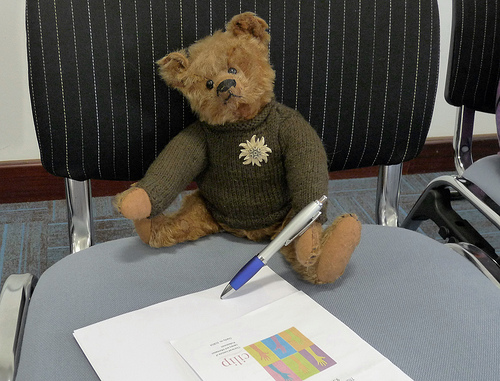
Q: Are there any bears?
A: Yes, there is a bear.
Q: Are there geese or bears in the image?
A: Yes, there is a bear.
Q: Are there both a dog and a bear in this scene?
A: No, there is a bear but no dogs.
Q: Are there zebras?
A: No, there are no zebras.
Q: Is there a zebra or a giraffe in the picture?
A: No, there are no zebras or giraffes.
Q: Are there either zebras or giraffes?
A: No, there are no zebras or giraffes.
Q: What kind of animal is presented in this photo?
A: The animal is a bear.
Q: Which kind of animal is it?
A: The animal is a bear.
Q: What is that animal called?
A: That is a bear.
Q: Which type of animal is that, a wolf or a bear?
A: That is a bear.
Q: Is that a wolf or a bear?
A: That is a bear.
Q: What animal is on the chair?
A: The bear is on the chair.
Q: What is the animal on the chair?
A: The animal is a bear.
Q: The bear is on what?
A: The bear is on the chair.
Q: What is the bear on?
A: The bear is on the chair.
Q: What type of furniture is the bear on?
A: The bear is on the chair.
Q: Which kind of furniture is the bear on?
A: The bear is on the chair.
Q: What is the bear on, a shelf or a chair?
A: The bear is on a chair.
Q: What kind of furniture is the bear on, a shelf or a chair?
A: The bear is on a chair.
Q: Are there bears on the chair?
A: Yes, there is a bear on the chair.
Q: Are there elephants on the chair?
A: No, there is a bear on the chair.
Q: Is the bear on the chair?
A: Yes, the bear is on the chair.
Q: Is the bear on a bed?
A: No, the bear is on the chair.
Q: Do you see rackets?
A: No, there are no rackets.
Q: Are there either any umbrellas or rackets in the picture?
A: No, there are no rackets or umbrellas.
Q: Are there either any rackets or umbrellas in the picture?
A: No, there are no rackets or umbrellas.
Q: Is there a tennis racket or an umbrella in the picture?
A: No, there are no rackets or umbrellas.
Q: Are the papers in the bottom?
A: Yes, the papers are in the bottom of the image.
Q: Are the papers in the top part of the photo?
A: No, the papers are in the bottom of the image.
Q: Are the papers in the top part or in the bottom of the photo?
A: The papers are in the bottom of the image.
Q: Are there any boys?
A: No, there are no boys.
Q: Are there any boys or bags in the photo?
A: No, there are no boys or bags.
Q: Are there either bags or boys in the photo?
A: No, there are no boys or bags.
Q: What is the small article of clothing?
A: The clothing item is a sweater.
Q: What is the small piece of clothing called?
A: The clothing item is a sweater.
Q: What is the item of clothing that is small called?
A: The clothing item is a sweater.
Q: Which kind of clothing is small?
A: The clothing is a sweater.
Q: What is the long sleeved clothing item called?
A: The clothing item is a sweater.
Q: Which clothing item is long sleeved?
A: The clothing item is a sweater.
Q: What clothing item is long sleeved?
A: The clothing item is a sweater.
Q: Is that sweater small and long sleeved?
A: Yes, the sweater is small and long sleeved.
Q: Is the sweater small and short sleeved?
A: No, the sweater is small but long sleeved.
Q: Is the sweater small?
A: Yes, the sweater is small.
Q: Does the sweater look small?
A: Yes, the sweater is small.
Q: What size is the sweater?
A: The sweater is small.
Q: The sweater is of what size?
A: The sweater is small.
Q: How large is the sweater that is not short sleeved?
A: The sweater is small.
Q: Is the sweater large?
A: No, the sweater is small.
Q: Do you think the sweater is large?
A: No, the sweater is small.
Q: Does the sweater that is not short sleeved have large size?
A: No, the sweater is small.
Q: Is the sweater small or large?
A: The sweater is small.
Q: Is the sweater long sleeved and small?
A: Yes, the sweater is long sleeved and small.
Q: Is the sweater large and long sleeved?
A: No, the sweater is long sleeved but small.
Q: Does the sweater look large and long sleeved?
A: No, the sweater is long sleeved but small.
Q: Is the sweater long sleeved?
A: Yes, the sweater is long sleeved.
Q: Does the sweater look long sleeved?
A: Yes, the sweater is long sleeved.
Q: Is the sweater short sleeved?
A: No, the sweater is long sleeved.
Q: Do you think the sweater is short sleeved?
A: No, the sweater is long sleeved.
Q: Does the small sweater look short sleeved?
A: No, the sweater is long sleeved.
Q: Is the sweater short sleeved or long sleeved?
A: The sweater is long sleeved.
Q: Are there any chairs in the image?
A: Yes, there is a chair.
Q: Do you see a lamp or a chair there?
A: Yes, there is a chair.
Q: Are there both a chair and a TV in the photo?
A: No, there is a chair but no televisions.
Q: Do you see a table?
A: No, there are no tables.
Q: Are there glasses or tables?
A: No, there are no tables or glasses.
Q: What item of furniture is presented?
A: The piece of furniture is a chair.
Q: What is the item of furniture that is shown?
A: The piece of furniture is a chair.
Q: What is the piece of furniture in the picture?
A: The piece of furniture is a chair.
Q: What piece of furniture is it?
A: The piece of furniture is a chair.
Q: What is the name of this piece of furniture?
A: That is a chair.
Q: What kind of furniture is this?
A: That is a chair.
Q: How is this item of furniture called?
A: That is a chair.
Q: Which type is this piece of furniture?
A: That is a chair.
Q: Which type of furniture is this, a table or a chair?
A: That is a chair.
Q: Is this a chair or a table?
A: This is a chair.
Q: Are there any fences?
A: No, there are no fences.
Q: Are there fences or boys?
A: No, there are no fences or boys.